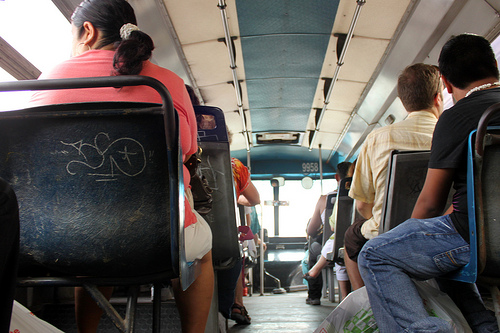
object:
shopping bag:
[313, 285, 380, 332]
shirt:
[427, 88, 500, 245]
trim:
[229, 143, 337, 173]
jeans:
[357, 213, 499, 332]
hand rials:
[306, 0, 368, 152]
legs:
[150, 281, 163, 332]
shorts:
[183, 208, 213, 262]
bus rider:
[25, 0, 215, 332]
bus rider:
[356, 33, 499, 332]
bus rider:
[342, 63, 446, 291]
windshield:
[251, 178, 337, 237]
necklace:
[462, 78, 497, 105]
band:
[119, 23, 142, 40]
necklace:
[464, 81, 499, 97]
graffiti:
[50, 132, 148, 182]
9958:
[300, 161, 319, 172]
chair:
[0, 74, 203, 332]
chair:
[435, 101, 499, 332]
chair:
[379, 148, 432, 235]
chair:
[190, 105, 242, 332]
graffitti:
[194, 156, 226, 191]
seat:
[326, 177, 353, 303]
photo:
[0, 0, 499, 331]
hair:
[71, 0, 154, 93]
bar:
[217, 0, 253, 152]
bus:
[0, 0, 499, 332]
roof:
[154, 0, 420, 150]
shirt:
[23, 49, 198, 229]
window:
[250, 179, 278, 238]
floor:
[217, 288, 343, 332]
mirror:
[270, 176, 286, 188]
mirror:
[300, 176, 313, 189]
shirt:
[347, 111, 438, 241]